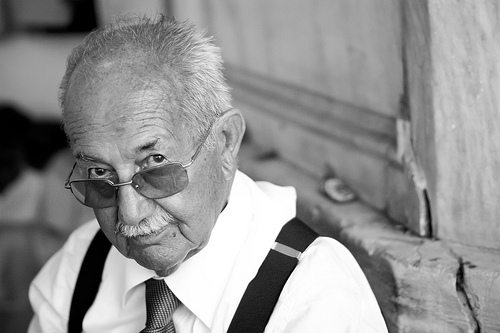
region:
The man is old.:
[21, 16, 391, 331]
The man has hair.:
[21, 17, 401, 331]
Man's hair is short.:
[35, 7, 256, 288]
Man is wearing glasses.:
[43, 10, 253, 283]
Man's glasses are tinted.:
[54, 100, 224, 210]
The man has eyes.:
[39, 12, 256, 285]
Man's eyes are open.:
[57, 17, 248, 283]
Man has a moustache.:
[53, 5, 261, 292]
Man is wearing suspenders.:
[16, 13, 385, 330]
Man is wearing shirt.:
[17, 7, 391, 331]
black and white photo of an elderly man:
[9, 10, 499, 308]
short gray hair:
[48, 10, 228, 93]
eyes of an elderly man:
[70, 142, 166, 176]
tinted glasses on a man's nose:
[55, 160, 192, 213]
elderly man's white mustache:
[115, 209, 172, 241]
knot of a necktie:
[126, 273, 186, 331]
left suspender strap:
[236, 210, 323, 332]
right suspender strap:
[56, 226, 108, 327]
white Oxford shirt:
[26, 216, 326, 331]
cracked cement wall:
[402, 217, 492, 332]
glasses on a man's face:
[61, 115, 218, 208]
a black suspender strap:
[218, 212, 318, 330]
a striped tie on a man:
[145, 269, 178, 331]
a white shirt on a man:
[26, 170, 404, 331]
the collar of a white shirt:
[160, 268, 232, 330]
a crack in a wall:
[401, 172, 489, 331]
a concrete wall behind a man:
[166, 3, 496, 328]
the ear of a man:
[212, 100, 253, 177]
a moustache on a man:
[111, 204, 169, 237]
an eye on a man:
[141, 149, 175, 166]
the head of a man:
[49, 5, 248, 275]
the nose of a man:
[112, 162, 164, 230]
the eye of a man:
[134, 146, 175, 179]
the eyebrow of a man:
[134, 134, 166, 156]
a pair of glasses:
[46, 93, 233, 220]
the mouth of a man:
[118, 216, 181, 256]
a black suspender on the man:
[210, 212, 327, 331]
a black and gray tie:
[133, 270, 185, 331]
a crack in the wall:
[448, 252, 487, 331]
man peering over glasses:
[60, 19, 322, 322]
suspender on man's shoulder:
[240, 220, 319, 315]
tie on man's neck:
[135, 269, 179, 328]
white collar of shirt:
[119, 253, 229, 315]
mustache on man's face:
[114, 212, 184, 244]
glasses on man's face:
[70, 157, 203, 209]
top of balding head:
[90, 23, 168, 97]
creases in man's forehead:
[67, 97, 169, 148]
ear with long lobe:
[209, 106, 251, 181]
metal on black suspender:
[262, 236, 305, 271]